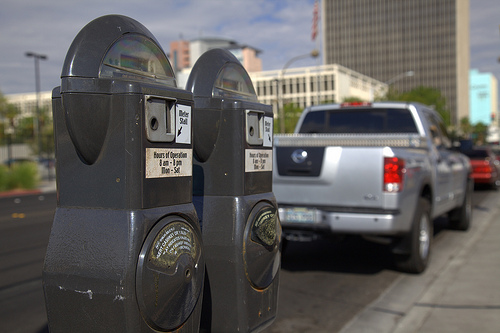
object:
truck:
[269, 103, 471, 272]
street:
[0, 186, 489, 333]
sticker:
[140, 145, 195, 179]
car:
[462, 141, 499, 186]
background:
[0, 0, 499, 333]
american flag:
[310, 3, 321, 39]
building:
[248, 63, 390, 115]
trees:
[0, 90, 23, 166]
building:
[321, 0, 470, 128]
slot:
[161, 98, 175, 132]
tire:
[389, 195, 437, 276]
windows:
[400, 61, 403, 73]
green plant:
[0, 158, 40, 189]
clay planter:
[1, 188, 44, 195]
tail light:
[383, 184, 400, 193]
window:
[294, 108, 420, 135]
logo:
[360, 191, 384, 205]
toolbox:
[273, 133, 430, 154]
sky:
[0, 0, 499, 98]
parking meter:
[183, 49, 279, 330]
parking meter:
[44, 13, 207, 331]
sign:
[143, 149, 192, 177]